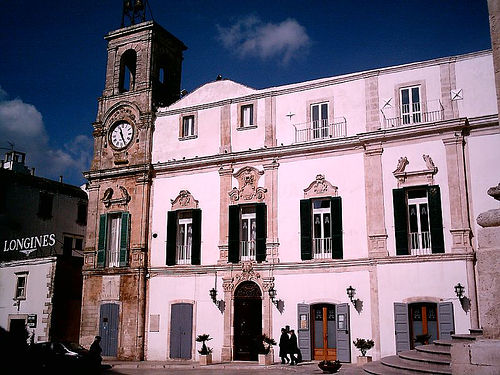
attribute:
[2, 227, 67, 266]
sign — Longines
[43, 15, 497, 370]
building — old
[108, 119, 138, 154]
clock — large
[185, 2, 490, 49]
sky — mostly clear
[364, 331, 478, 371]
staircase — large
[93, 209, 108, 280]
shutters — green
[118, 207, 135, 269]
shutters — green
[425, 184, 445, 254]
shutter — black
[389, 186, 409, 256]
shutter — black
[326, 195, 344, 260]
shutter — black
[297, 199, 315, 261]
shutter — black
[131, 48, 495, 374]
building — two toned pink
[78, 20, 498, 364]
building — large, pink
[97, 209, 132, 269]
window — white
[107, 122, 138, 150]
clock — white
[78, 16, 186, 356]
building — old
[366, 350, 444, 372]
step — round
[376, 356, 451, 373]
step — round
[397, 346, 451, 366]
step — round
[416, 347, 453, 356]
step — round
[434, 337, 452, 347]
step — round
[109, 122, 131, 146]
face — white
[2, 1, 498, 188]
sky — blue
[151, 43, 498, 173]
floor — third floor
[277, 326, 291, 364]
person — one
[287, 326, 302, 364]
person — one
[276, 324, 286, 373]
person — one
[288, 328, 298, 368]
person — one